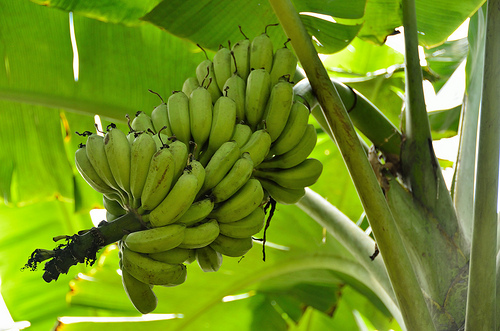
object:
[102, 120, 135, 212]
bananas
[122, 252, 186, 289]
banana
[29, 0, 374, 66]
leaf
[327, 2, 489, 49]
leaves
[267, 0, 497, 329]
tree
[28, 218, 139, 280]
stem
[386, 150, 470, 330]
trunk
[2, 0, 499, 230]
background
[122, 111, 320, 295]
bottom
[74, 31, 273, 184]
top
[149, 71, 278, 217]
middle